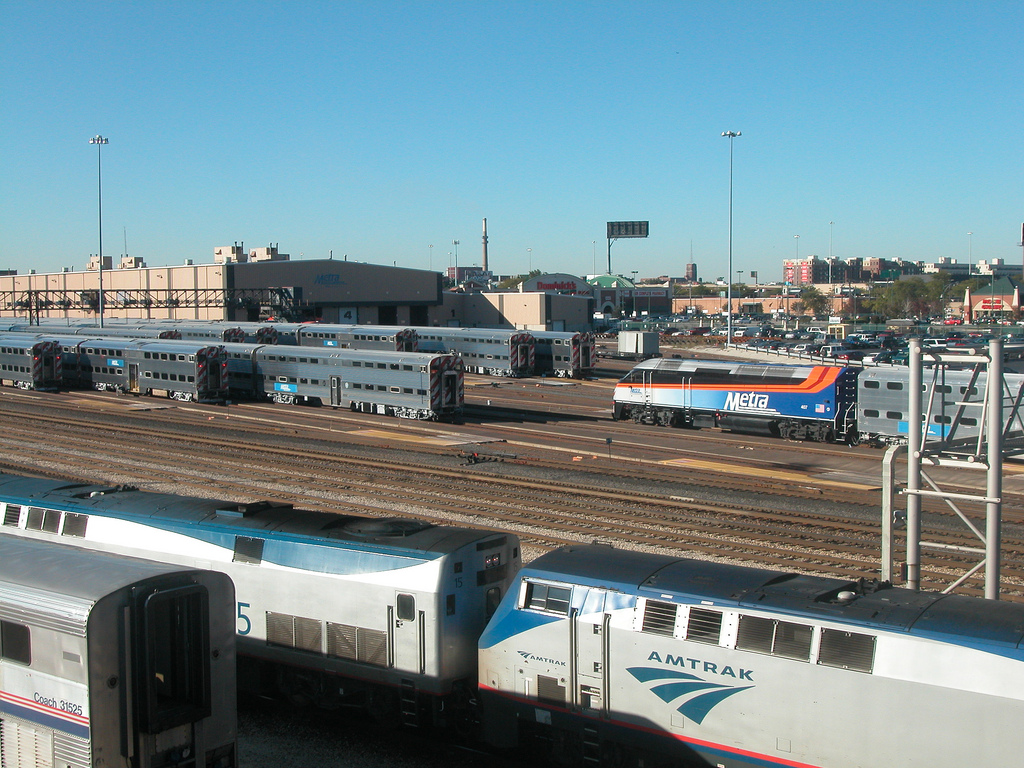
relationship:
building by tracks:
[515, 270, 674, 321] [3, 398, 1021, 608]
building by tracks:
[943, 278, 1021, 324] [3, 398, 1021, 608]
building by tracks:
[784, 254, 824, 290] [3, 398, 1021, 608]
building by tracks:
[445, 286, 597, 332] [3, 398, 1021, 608]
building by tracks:
[4, 241, 445, 328] [3, 398, 1021, 608]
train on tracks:
[5, 451, 1020, 764] [3, 398, 1021, 608]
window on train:
[816, 626, 874, 675] [475, 537, 1023, 766]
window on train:
[733, 613, 816, 670] [475, 537, 1023, 766]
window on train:
[523, 581, 574, 619] [475, 537, 1023, 766]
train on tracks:
[74, 335, 224, 402] [6, 402, 1021, 627]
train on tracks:
[253, 343, 469, 429] [6, 402, 1021, 627]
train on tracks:
[475, 537, 1023, 766] [6, 402, 1021, 627]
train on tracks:
[6, 456, 519, 748] [6, 402, 1021, 627]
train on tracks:
[3, 330, 65, 394] [6, 402, 1021, 627]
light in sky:
[714, 121, 746, 140] [6, 5, 1022, 290]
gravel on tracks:
[674, 477, 709, 496] [4, 319, 870, 575]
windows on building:
[70, 126, 655, 519] [45, 119, 650, 502]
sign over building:
[605, 219, 656, 238] [525, 267, 674, 315]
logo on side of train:
[625, 652, 753, 725] [475, 537, 1023, 766]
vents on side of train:
[639, 601, 723, 644] [475, 537, 1023, 766]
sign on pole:
[607, 220, 650, 238] [600, 235, 616, 286]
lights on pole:
[88, 131, 108, 148] [93, 143, 104, 261]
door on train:
[316, 368, 349, 432] [0, 334, 467, 415]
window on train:
[257, 618, 488, 755] [2, 470, 522, 748]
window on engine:
[627, 368, 644, 387] [619, 349, 858, 442]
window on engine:
[864, 377, 880, 391] [619, 349, 858, 442]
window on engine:
[864, 409, 881, 419] [619, 349, 858, 442]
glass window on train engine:
[227, 528, 266, 589] [0, 519, 262, 751]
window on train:
[367, 381, 391, 394] [613, 346, 860, 448]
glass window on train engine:
[526, 580, 546, 609] [464, 535, 1021, 763]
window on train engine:
[527, 583, 576, 615] [477, 540, 1024, 763]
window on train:
[618, 369, 642, 385] [601, 345, 1020, 448]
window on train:
[622, 363, 808, 389] [605, 351, 858, 440]